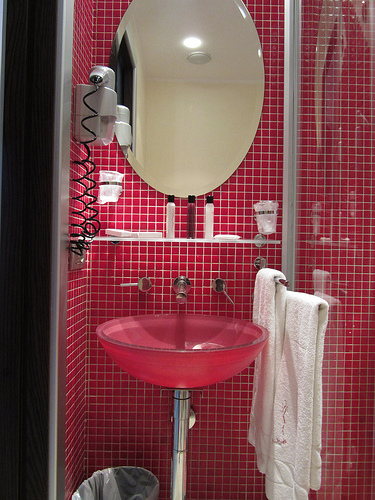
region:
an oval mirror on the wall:
[103, 0, 266, 198]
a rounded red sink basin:
[92, 311, 274, 389]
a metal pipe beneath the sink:
[169, 387, 192, 498]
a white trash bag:
[69, 466, 159, 497]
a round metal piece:
[184, 408, 195, 431]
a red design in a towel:
[275, 394, 291, 450]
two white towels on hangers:
[248, 267, 328, 498]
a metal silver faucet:
[172, 273, 191, 309]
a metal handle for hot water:
[122, 274, 151, 291]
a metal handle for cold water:
[211, 272, 237, 310]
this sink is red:
[64, 283, 286, 393]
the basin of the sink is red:
[91, 286, 292, 393]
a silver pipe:
[158, 389, 216, 499]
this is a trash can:
[74, 457, 168, 499]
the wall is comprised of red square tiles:
[79, 7, 113, 48]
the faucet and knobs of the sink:
[110, 257, 254, 314]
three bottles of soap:
[155, 181, 226, 238]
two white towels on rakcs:
[244, 251, 344, 498]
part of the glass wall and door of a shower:
[298, 8, 374, 488]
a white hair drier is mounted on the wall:
[69, 53, 131, 159]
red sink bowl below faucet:
[103, 305, 257, 407]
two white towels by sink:
[243, 264, 325, 486]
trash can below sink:
[81, 462, 168, 498]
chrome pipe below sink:
[165, 390, 195, 495]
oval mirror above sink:
[109, 6, 262, 213]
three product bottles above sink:
[167, 193, 217, 247]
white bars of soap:
[102, 220, 164, 244]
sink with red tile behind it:
[86, 202, 335, 450]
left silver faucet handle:
[118, 271, 150, 293]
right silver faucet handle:
[209, 275, 236, 305]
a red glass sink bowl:
[96, 311, 270, 386]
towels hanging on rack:
[253, 267, 322, 496]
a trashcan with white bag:
[70, 465, 158, 499]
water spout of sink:
[172, 277, 189, 301]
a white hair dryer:
[82, 61, 115, 89]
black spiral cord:
[70, 77, 103, 254]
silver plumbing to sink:
[171, 388, 202, 498]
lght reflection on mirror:
[178, 34, 204, 52]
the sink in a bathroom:
[99, 308, 270, 392]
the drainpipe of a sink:
[165, 385, 196, 498]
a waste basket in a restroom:
[69, 452, 163, 498]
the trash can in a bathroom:
[63, 458, 159, 498]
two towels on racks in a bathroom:
[251, 262, 334, 497]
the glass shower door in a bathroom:
[299, 8, 371, 479]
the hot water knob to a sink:
[117, 272, 154, 298]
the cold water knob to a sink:
[208, 271, 242, 311]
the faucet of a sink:
[164, 264, 196, 310]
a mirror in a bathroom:
[107, 1, 267, 202]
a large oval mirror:
[110, 2, 269, 190]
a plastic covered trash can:
[68, 466, 154, 496]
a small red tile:
[205, 396, 217, 405]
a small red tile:
[223, 398, 233, 406]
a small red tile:
[103, 401, 113, 415]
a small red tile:
[333, 443, 344, 454]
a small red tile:
[329, 373, 337, 383]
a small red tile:
[326, 413, 336, 422]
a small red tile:
[338, 367, 343, 375]